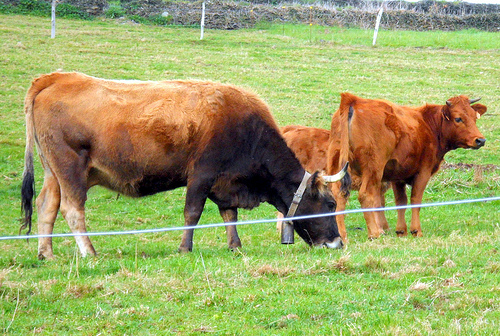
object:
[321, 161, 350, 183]
horn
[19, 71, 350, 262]
cow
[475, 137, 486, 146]
nose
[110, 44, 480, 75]
pasture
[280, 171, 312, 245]
collar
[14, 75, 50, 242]
tail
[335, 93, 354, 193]
tail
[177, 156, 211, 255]
leg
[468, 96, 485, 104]
horn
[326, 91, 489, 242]
bull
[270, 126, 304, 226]
neck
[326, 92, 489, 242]
cow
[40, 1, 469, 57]
fence